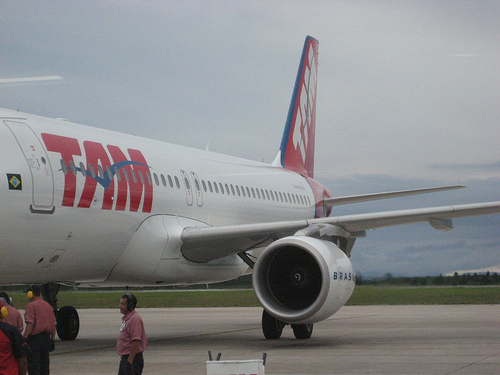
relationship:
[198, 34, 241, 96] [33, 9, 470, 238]
cloud in sky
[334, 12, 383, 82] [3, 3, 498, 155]
cloud in sky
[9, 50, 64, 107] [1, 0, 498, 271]
cloud in sky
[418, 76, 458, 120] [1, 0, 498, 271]
cloud in sky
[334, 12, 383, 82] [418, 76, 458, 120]
cloud in cloud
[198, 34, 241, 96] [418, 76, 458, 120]
cloud in cloud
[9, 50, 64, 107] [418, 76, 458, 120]
cloud in cloud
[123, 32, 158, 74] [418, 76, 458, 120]
cloud in cloud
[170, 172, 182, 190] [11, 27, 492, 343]
window on airplane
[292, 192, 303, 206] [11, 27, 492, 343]
window on airplane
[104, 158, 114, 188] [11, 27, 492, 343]
window on airplane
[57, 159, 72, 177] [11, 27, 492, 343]
window on airplane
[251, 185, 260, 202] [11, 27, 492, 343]
window on airplane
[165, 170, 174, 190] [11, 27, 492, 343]
window on airplane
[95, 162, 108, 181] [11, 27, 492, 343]
window on airplane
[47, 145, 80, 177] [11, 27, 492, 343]
window on airplane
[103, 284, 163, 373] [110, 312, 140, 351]
man wearing shirt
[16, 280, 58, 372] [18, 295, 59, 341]
man wearing shirt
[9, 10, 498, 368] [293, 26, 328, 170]
airplane has tail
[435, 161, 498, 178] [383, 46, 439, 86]
cloud in sky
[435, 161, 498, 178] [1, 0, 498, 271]
cloud in sky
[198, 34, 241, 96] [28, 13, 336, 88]
cloud in sky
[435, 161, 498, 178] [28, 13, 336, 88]
cloud in sky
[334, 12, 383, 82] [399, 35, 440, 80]
cloud in sky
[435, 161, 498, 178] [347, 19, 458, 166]
cloud in sky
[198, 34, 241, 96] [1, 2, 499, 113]
cloud in sky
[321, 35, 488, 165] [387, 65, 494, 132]
clouds in sky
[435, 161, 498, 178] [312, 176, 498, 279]
cloud in blue sky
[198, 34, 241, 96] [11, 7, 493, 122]
cloud in sky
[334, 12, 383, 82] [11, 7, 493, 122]
cloud in sky